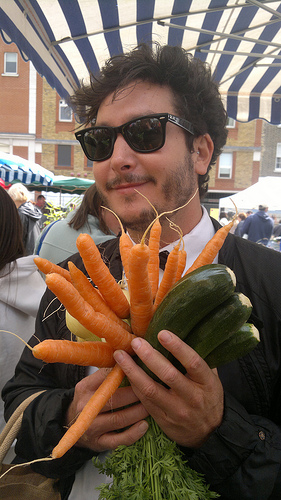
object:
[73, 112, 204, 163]
sunglasses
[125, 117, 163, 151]
crowd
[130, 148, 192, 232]
beard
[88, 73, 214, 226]
face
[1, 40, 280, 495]
man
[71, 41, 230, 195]
hair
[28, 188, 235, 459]
carrots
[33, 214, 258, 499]
vegetables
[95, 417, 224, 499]
heads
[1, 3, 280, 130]
canopy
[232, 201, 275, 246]
man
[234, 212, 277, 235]
sweater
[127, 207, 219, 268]
shirt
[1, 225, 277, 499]
jacket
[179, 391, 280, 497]
sleeve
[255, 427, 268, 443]
button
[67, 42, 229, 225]
head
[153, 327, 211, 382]
finger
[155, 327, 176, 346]
finger nail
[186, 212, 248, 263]
carrot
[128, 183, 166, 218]
stems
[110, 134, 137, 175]
nose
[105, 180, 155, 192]
mouth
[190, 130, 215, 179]
ear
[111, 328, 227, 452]
hand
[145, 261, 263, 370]
zucchinis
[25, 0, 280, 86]
frame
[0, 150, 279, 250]
market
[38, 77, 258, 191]
wall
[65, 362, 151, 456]
hand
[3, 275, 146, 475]
arm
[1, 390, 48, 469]
handle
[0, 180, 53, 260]
shoppers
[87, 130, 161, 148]
eyes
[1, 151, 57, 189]
umbrella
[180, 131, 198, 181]
sideburns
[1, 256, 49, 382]
sweatshirt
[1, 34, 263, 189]
building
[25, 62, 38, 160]
border